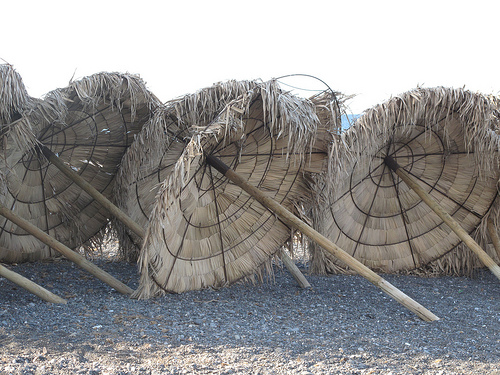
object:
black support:
[389, 168, 417, 270]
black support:
[400, 165, 484, 220]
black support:
[385, 118, 397, 157]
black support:
[393, 110, 460, 155]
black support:
[354, 152, 390, 160]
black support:
[255, 199, 294, 230]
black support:
[209, 163, 228, 283]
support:
[182, 174, 226, 213]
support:
[39, 164, 52, 257]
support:
[163, 213, 193, 290]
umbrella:
[0, 63, 43, 132]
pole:
[277, 247, 313, 289]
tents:
[309, 87, 500, 275]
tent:
[130, 73, 341, 298]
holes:
[78, 159, 103, 168]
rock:
[345, 344, 368, 362]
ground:
[33, 309, 439, 371]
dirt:
[83, 306, 124, 335]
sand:
[322, 334, 371, 356]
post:
[36, 144, 147, 240]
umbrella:
[111, 80, 258, 265]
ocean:
[343, 112, 351, 127]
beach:
[5, 334, 494, 370]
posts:
[0, 264, 68, 306]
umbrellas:
[1, 72, 164, 265]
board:
[224, 169, 441, 324]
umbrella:
[426, 194, 500, 270]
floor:
[0, 305, 314, 373]